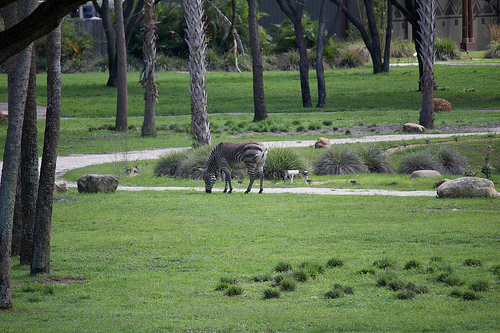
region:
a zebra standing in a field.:
[177, 129, 276, 199]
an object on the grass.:
[70, 171, 132, 206]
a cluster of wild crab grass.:
[213, 254, 496, 306]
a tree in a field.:
[178, 0, 225, 156]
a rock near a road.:
[314, 137, 336, 150]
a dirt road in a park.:
[20, 123, 497, 207]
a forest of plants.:
[3, 6, 496, 63]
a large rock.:
[71, 163, 121, 216]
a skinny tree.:
[22, 0, 82, 289]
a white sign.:
[285, 162, 304, 182]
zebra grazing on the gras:
[186, 133, 279, 200]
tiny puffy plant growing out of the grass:
[220, 283, 247, 303]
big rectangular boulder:
[74, 171, 124, 198]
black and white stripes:
[242, 143, 264, 168]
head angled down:
[193, 154, 229, 196]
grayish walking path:
[28, 124, 499, 209]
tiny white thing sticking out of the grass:
[283, 166, 299, 184]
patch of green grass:
[21, 198, 496, 323]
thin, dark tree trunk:
[30, 36, 60, 274]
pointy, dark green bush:
[259, 140, 311, 180]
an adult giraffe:
[181, 133, 288, 202]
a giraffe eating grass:
[170, 115, 278, 219]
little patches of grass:
[208, 236, 485, 305]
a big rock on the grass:
[399, 167, 493, 210]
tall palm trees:
[175, 2, 236, 142]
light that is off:
[269, 157, 302, 184]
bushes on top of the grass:
[150, 44, 363, 78]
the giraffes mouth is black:
[194, 185, 222, 199]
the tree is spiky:
[170, 3, 218, 133]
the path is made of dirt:
[44, 140, 204, 163]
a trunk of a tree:
[186, 42, 213, 141]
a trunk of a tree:
[24, 98, 65, 268]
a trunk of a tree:
[292, 30, 314, 108]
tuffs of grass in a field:
[256, 278, 283, 303]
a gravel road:
[107, 143, 156, 163]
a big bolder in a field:
[431, 171, 496, 200]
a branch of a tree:
[228, 22, 251, 75]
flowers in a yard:
[313, 146, 373, 173]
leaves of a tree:
[274, 22, 296, 49]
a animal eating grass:
[198, 139, 270, 196]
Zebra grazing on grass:
[193, 130, 290, 224]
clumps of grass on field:
[218, 254, 494, 311]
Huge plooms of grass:
[308, 127, 474, 174]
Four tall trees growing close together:
[2, 72, 81, 330]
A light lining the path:
[281, 159, 307, 188]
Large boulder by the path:
[60, 132, 127, 219]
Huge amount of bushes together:
[272, 26, 377, 68]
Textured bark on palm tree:
[181, 17, 231, 152]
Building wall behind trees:
[452, 10, 497, 67]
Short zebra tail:
[244, 131, 279, 165]